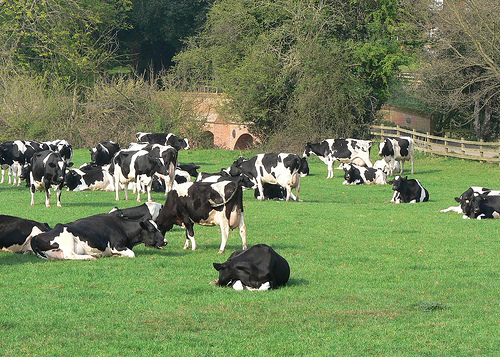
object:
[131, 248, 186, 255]
cow shadow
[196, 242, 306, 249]
shadow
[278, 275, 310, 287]
shadow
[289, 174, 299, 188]
udder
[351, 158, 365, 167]
udder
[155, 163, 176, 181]
udder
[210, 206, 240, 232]
udder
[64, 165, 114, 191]
cow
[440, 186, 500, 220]
cow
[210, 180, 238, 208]
cow's tail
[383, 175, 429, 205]
cow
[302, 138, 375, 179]
cow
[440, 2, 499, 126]
bare tree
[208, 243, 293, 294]
cow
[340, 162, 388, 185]
cow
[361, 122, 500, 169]
fence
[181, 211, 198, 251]
legs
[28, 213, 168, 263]
cow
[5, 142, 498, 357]
grass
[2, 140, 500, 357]
field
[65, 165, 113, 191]
cows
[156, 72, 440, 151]
bridge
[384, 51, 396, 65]
leaf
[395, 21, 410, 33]
leaf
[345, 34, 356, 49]
leaf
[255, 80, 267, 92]
leaf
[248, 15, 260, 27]
leaf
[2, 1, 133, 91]
tree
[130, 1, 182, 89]
tree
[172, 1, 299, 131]
tree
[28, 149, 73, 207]
cow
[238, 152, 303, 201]
cow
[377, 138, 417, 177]
cow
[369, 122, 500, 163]
bridge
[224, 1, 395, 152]
tree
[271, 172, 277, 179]
spot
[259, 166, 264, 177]
spot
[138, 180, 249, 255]
cow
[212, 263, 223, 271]
ear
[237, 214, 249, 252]
leg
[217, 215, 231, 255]
leg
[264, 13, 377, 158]
tree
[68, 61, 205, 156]
tree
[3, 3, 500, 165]
background